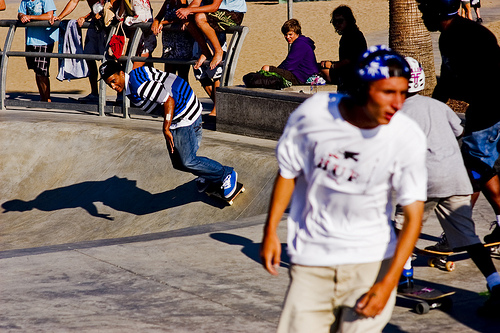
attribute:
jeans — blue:
[171, 99, 255, 201]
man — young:
[102, 55, 246, 205]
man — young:
[97, 58, 259, 228]